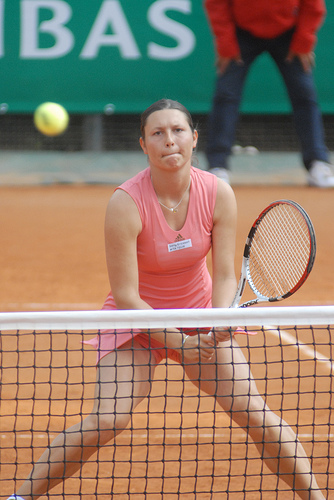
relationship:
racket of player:
[233, 199, 316, 306] [8, 98, 326, 500]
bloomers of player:
[135, 334, 179, 364] [8, 98, 326, 500]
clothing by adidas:
[95, 164, 218, 361] [175, 231, 187, 243]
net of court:
[0, 305, 333, 499] [2, 179, 333, 305]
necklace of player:
[150, 171, 192, 214] [8, 98, 326, 500]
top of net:
[0, 306, 331, 331] [0, 305, 333, 499]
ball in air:
[34, 100, 70, 137] [12, 75, 98, 165]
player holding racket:
[8, 98, 326, 500] [233, 199, 316, 306]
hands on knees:
[213, 52, 317, 73] [213, 78, 315, 105]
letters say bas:
[16, 0, 199, 60] [17, 3, 205, 67]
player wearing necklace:
[8, 98, 326, 500] [150, 171, 192, 214]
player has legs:
[8, 98, 326, 500] [9, 345, 329, 499]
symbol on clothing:
[173, 231, 186, 241] [95, 164, 218, 361]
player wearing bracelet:
[8, 98, 326, 500] [178, 333, 192, 349]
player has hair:
[8, 98, 326, 500] [138, 97, 196, 142]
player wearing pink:
[8, 98, 326, 500] [95, 164, 218, 361]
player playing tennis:
[8, 98, 326, 500] [34, 100, 318, 309]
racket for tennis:
[233, 199, 316, 306] [34, 100, 318, 309]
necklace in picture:
[150, 171, 192, 214] [1, 1, 332, 500]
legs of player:
[9, 345, 161, 500] [8, 98, 326, 500]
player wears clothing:
[8, 98, 326, 500] [95, 164, 218, 361]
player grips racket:
[8, 98, 326, 500] [233, 199, 316, 306]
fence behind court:
[0, 113, 333, 154] [2, 179, 333, 305]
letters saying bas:
[16, 0, 199, 60] [17, 3, 205, 67]